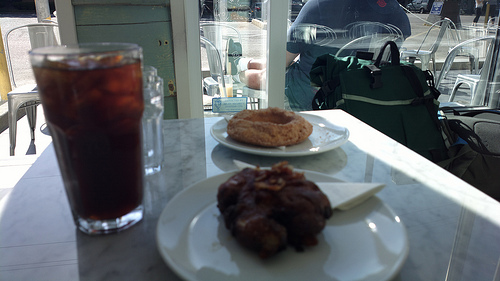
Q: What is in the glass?
A: Soda.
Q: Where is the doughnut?
A: On the plate.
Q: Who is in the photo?
A: One person.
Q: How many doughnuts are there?
A: Two.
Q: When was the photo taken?
A: Daytime.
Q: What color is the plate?
A: White.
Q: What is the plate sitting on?
A: The counter.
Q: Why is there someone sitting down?
A: He is a customer.